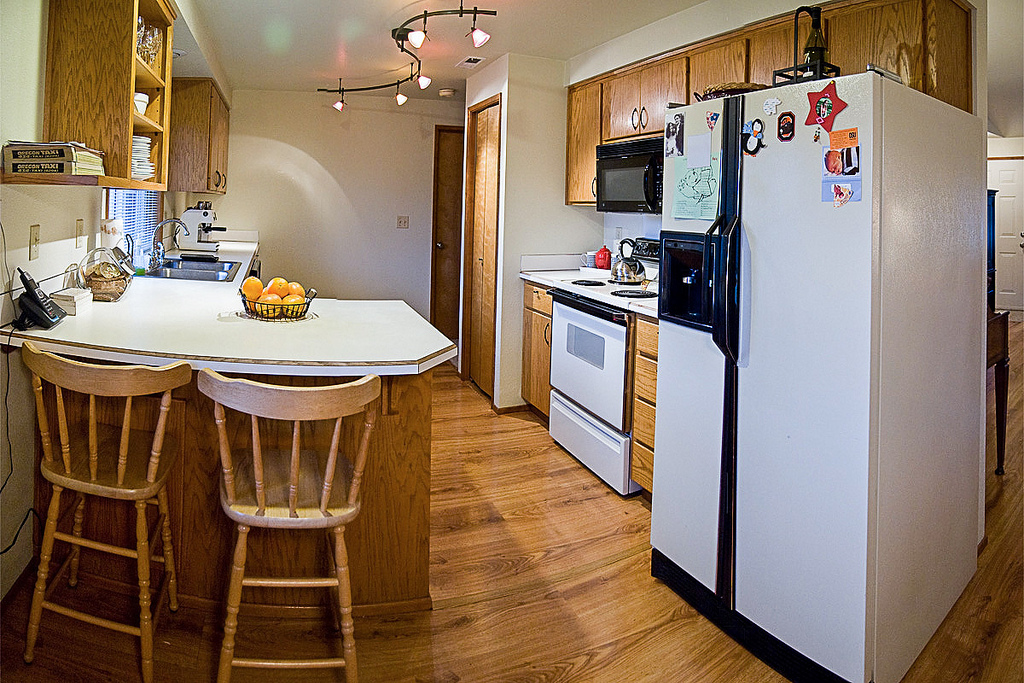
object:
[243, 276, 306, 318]
fruit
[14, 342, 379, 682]
chairs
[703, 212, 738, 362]
handles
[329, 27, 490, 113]
lights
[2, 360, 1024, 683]
floor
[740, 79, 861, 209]
magnets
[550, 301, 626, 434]
door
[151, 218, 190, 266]
faucet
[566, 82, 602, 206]
cabinet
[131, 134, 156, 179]
plates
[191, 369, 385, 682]
chair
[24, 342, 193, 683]
chair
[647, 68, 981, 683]
fridge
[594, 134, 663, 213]
microwave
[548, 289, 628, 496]
oven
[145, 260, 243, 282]
sink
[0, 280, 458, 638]
table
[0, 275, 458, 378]
counter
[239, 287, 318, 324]
bowl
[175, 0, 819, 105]
ceiling